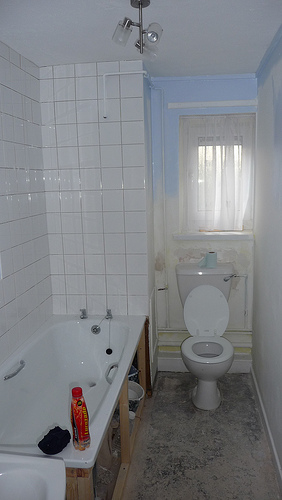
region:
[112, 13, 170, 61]
Silver light on a ceiling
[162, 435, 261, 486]
Unfinished floor in a bathroom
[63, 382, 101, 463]
Red bottle on a tub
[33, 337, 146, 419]
White bathtub with unfinished side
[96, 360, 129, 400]
Silver handle on a bathtub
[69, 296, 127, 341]
Silver faucet on a bathtub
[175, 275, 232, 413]
Opened white toilet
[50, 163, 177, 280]
Tiled bathtub surround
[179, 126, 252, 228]
White curtain in a window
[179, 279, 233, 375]
Opened toilet seat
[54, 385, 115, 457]
there is a bottle of lucozade on the bathtub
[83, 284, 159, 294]
the tiles are white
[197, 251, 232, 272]
there is a toilet paper on the toilet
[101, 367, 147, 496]
there are buckets underneath the bathtub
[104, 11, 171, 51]
the lights are hanging on the ceiling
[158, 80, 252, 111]
the wall is blue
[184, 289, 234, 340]
the toilet lid is up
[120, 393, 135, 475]
the wooden poles support the bath tub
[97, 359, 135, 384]
the handles are metalic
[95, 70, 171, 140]
the bars are made of metal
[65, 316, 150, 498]
the bathtub is under contruction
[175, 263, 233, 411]
the toilet is white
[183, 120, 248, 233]
the window has curtains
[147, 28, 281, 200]
the wall is painted blue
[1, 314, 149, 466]
the tub is white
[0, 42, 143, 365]
the wall is tiled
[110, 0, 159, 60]
the light fixture is metal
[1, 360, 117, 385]
the tub has handles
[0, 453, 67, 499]
the sink is white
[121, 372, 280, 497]
the floor is unfinished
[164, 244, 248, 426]
White toilet open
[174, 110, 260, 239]
Window with sun shining behind curtains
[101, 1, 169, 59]
Light fixture with three lights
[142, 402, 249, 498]
Bare floor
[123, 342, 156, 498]
Half-constructed cabinets with paint cans inside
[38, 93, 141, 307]
White tiled bathroom wall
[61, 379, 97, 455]
Bottle of a sports drink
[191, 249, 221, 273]
Roll of toilet paper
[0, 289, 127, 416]
Bathtub with handles on sides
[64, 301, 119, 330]
Silver faucets on bathtub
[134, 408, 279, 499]
Gray and black dirty floor of the bathroom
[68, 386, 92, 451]
A red bottle on the edge of the tub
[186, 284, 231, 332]
A white toilet seat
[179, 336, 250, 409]
A white toilet bowl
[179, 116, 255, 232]
A white curtain on a window above the toilet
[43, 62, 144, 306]
White square wall tiles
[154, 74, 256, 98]
Part of a blue painted wall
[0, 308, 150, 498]
A white bathtub opened on the right side exposing wood and objects inside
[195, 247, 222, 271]
A small roll of colored toilet tissue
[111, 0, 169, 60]
A light fixture on the ceiling